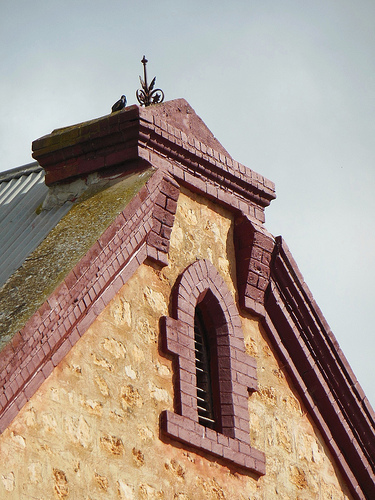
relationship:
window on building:
[158, 248, 279, 471] [2, 94, 373, 499]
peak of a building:
[31, 55, 274, 222] [2, 94, 373, 499]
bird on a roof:
[112, 95, 127, 113] [21, 48, 249, 177]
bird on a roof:
[112, 95, 127, 113] [0, 47, 373, 459]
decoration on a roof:
[136, 55, 164, 106] [30, 102, 318, 343]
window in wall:
[193, 286, 235, 440] [0, 172, 360, 498]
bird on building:
[112, 95, 127, 113] [11, 52, 348, 499]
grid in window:
[194, 318, 215, 428] [186, 306, 240, 435]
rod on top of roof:
[114, 61, 176, 97] [1, 82, 264, 275]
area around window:
[158, 258, 267, 476] [170, 259, 252, 446]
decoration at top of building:
[130, 52, 176, 105] [2, 94, 373, 499]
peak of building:
[140, 98, 234, 160] [2, 94, 373, 499]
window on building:
[193, 286, 235, 440] [13, 85, 368, 483]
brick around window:
[0, 107, 375, 500] [190, 279, 232, 439]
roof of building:
[0, 168, 136, 339] [2, 94, 373, 499]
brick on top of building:
[0, 107, 375, 500] [2, 94, 373, 499]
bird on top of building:
[105, 91, 131, 117] [2, 94, 373, 499]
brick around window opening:
[158, 257, 267, 478] [194, 293, 232, 434]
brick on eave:
[0, 107, 375, 500] [261, 245, 373, 498]